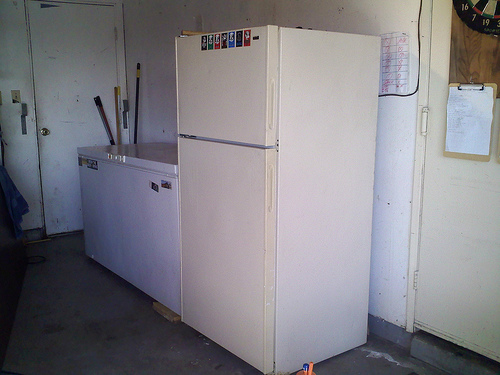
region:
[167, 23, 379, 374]
Fridge is in room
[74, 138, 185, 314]
freezer is next to fridge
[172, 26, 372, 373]
fridge is next to freezer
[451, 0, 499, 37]
dartboard hangs on wall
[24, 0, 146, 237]
door is closed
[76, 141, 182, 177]
lid is closed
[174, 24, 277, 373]
door is closed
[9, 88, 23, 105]
light switch is on wall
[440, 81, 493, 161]
clipboard hangs on wall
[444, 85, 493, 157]
paper is on clipboard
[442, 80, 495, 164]
a clipboard on the wall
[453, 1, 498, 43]
corner of a dartboard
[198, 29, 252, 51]
stickers on the freezer door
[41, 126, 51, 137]
a brass door knob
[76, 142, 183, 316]
a large white storage freezer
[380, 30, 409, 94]
paper stuck on the wall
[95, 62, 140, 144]
a collection of handles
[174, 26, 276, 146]
the freezer door is closed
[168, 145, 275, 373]
the refrigerator door is closed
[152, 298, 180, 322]
wood under the freezer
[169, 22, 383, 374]
white refrigerator and freezer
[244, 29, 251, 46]
red magnet on refrigerator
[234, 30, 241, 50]
black magnet on refrigerator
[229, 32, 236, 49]
blue magnet on refrigerator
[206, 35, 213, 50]
green magnet on refrigerator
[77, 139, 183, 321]
top open freezer on floor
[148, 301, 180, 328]
unfinished wood block under freezer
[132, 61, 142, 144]
black plastic broom handle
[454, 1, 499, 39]
dart board on wall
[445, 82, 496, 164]
clip board on wall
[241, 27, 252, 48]
red rectangle tag on the fridge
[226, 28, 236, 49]
blue rectangle tag on the fridge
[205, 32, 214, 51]
green rectangle tag on the fridge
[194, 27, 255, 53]
a bunch of tags on a fridge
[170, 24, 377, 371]
a white refrigerator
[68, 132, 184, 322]
a white deep freezer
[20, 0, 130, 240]
white dirty door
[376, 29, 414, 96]
a piece of paper on the wall with red print on it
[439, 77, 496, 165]
a piece of paper on a yellow clipboard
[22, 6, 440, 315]
a refrigerator and freezer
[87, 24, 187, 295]
the freezer is white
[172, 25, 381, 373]
the refrigerator is off white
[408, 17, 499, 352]
a door to the room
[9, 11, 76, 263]
another door to the room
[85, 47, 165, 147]
sticks in the room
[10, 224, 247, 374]
a stone floor on the ground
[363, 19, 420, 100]
a sign on the wall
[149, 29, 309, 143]
a freezer unit on the refrigerator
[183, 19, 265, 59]
stickers on the refrigerator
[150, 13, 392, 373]
The fridge is white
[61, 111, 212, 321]
The freezer is white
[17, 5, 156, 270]
The door is white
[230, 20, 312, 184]
Sticker on the fridge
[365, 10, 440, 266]
Paper on the wall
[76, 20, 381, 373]
Refrigerator and a freezer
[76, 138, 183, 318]
Rectangular white freezer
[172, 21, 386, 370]
Two door white refrigerator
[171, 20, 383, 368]
Rectangular white refrigerator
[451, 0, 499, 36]
Partially seen dart wheel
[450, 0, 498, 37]
Number 16 on the dart